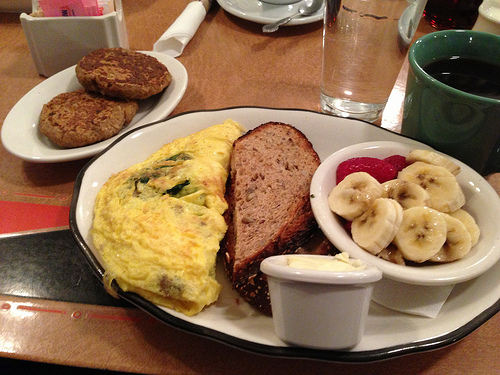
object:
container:
[18, 1, 141, 76]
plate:
[65, 104, 500, 365]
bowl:
[309, 140, 499, 286]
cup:
[260, 251, 382, 353]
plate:
[0, 49, 189, 164]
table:
[6, 12, 473, 367]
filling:
[128, 148, 201, 211]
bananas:
[328, 148, 480, 263]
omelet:
[90, 117, 240, 316]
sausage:
[72, 46, 174, 100]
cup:
[400, 29, 499, 174]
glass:
[322, 2, 392, 119]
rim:
[407, 29, 499, 104]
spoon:
[262, 0, 323, 34]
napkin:
[153, 2, 210, 60]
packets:
[37, 1, 103, 16]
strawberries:
[336, 156, 397, 183]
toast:
[223, 119, 320, 314]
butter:
[288, 251, 365, 271]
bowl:
[258, 0, 301, 8]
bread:
[224, 120, 316, 317]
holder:
[20, 14, 129, 76]